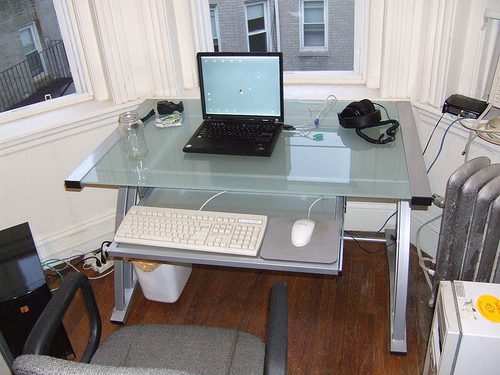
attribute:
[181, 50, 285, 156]
laptop — black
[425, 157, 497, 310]
wall heater — gray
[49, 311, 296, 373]
cushion — gray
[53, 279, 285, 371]
chair — gray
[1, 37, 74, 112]
balcony — part 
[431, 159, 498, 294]
radiator — old fashioned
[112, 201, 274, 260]
keyboard — white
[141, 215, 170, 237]
keys — white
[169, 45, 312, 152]
laptop computer — black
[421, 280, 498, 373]
processing unit — white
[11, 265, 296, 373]
chair — gray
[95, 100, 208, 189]
clear jar — tall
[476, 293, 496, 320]
sticker — yellow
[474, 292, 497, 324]
sticker — oval, yellow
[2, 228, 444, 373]
floor — wooden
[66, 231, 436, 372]
grain — dark brown, wood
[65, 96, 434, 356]
desk — gray, stark, functional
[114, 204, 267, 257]
keyboard — white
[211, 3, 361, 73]
window — part 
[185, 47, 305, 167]
laptop screen — black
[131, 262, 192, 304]
can — white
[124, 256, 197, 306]
waste basket — white